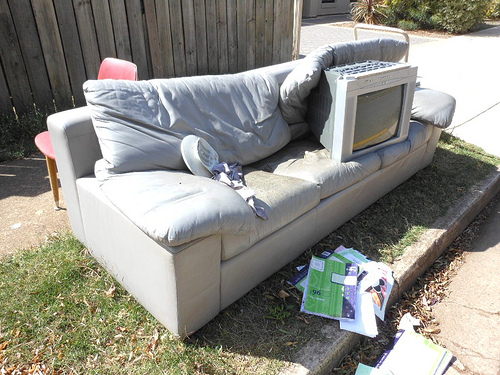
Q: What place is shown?
A: It is a street.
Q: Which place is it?
A: It is a street.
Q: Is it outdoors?
A: Yes, it is outdoors.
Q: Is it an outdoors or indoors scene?
A: It is outdoors.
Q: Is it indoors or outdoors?
A: It is outdoors.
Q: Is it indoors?
A: No, it is outdoors.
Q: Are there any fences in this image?
A: Yes, there is a fence.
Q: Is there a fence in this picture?
A: Yes, there is a fence.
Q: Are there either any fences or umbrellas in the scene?
A: Yes, there is a fence.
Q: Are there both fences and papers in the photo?
A: Yes, there are both a fence and papers.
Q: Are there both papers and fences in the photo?
A: Yes, there are both a fence and papers.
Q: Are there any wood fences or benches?
A: Yes, there is a wood fence.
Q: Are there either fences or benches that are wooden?
A: Yes, the fence is wooden.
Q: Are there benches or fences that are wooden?
A: Yes, the fence is wooden.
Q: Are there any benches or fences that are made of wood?
A: Yes, the fence is made of wood.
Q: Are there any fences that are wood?
A: Yes, there is a wood fence.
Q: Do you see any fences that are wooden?
A: Yes, there is a fence that is wooden.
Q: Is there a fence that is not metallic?
A: Yes, there is a wooden fence.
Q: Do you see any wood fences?
A: Yes, there is a fence that is made of wood.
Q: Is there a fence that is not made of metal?
A: Yes, there is a fence that is made of wood.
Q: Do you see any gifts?
A: No, there are no gifts.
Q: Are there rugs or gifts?
A: No, there are no gifts or rugs.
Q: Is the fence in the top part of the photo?
A: Yes, the fence is in the top of the image.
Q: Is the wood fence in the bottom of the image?
A: No, the fence is in the top of the image.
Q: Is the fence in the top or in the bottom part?
A: The fence is in the top of the image.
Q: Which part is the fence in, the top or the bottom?
A: The fence is in the top of the image.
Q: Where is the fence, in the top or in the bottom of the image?
A: The fence is in the top of the image.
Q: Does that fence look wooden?
A: Yes, the fence is wooden.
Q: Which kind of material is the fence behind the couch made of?
A: The fence is made of wood.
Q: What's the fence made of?
A: The fence is made of wood.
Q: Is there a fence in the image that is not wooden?
A: No, there is a fence but it is wooden.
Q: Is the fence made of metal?
A: No, the fence is made of wood.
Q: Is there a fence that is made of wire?
A: No, there is a fence but it is made of wood.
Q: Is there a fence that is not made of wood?
A: No, there is a fence but it is made of wood.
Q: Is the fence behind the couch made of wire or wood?
A: The fence is made of wood.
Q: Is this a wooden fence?
A: Yes, this is a wooden fence.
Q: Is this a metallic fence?
A: No, this is a wooden fence.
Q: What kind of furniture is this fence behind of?
A: The fence is behind the couch.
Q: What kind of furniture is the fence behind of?
A: The fence is behind the couch.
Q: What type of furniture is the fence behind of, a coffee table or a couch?
A: The fence is behind a couch.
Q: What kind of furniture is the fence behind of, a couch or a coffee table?
A: The fence is behind a couch.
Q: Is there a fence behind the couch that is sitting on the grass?
A: Yes, there is a fence behind the couch.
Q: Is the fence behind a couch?
A: Yes, the fence is behind a couch.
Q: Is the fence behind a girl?
A: No, the fence is behind a couch.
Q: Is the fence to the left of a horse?
A: No, the fence is to the left of a pillow.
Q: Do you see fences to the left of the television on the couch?
A: Yes, there is a fence to the left of the TV.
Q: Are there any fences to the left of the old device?
A: Yes, there is a fence to the left of the TV.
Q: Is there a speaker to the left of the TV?
A: No, there is a fence to the left of the TV.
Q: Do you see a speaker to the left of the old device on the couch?
A: No, there is a fence to the left of the TV.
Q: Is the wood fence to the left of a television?
A: Yes, the fence is to the left of a television.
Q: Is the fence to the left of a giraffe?
A: No, the fence is to the left of a television.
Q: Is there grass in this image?
A: Yes, there is grass.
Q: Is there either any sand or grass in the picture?
A: Yes, there is grass.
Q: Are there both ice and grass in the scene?
A: No, there is grass but no ice.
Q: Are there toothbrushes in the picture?
A: No, there are no toothbrushes.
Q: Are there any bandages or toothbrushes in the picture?
A: No, there are no toothbrushes or bandages.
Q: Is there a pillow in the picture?
A: Yes, there is a pillow.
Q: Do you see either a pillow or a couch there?
A: Yes, there is a pillow.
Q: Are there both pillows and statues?
A: No, there is a pillow but no statues.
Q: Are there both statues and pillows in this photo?
A: No, there is a pillow but no statues.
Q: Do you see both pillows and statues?
A: No, there is a pillow but no statues.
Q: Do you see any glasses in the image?
A: No, there are no glasses.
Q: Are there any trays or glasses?
A: No, there are no glasses or trays.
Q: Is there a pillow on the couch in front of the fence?
A: Yes, there is a pillow on the couch.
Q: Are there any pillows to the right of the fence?
A: Yes, there is a pillow to the right of the fence.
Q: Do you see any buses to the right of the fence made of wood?
A: No, there is a pillow to the right of the fence.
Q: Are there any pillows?
A: Yes, there is a pillow.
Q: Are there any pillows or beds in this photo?
A: Yes, there is a pillow.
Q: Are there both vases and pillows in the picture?
A: No, there is a pillow but no vases.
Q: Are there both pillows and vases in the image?
A: No, there is a pillow but no vases.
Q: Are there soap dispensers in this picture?
A: No, there are no soap dispensers.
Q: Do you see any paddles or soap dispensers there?
A: No, there are no soap dispensers or paddles.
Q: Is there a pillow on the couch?
A: Yes, there is a pillow on the couch.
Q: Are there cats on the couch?
A: No, there is a pillow on the couch.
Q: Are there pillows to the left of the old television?
A: Yes, there is a pillow to the left of the television.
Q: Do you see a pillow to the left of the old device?
A: Yes, there is a pillow to the left of the television.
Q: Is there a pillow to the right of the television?
A: No, the pillow is to the left of the television.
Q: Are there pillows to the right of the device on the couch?
A: No, the pillow is to the left of the television.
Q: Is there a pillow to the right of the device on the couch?
A: No, the pillow is to the left of the television.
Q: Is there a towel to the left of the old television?
A: No, there is a pillow to the left of the TV.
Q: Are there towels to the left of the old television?
A: No, there is a pillow to the left of the TV.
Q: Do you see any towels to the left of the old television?
A: No, there is a pillow to the left of the TV.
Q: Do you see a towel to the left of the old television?
A: No, there is a pillow to the left of the TV.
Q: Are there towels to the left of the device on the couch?
A: No, there is a pillow to the left of the TV.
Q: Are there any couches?
A: Yes, there is a couch.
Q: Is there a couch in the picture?
A: Yes, there is a couch.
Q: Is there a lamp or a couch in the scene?
A: Yes, there is a couch.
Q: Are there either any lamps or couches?
A: Yes, there is a couch.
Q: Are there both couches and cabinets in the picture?
A: No, there is a couch but no cabinets.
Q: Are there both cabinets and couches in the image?
A: No, there is a couch but no cabinets.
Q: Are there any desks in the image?
A: No, there are no desks.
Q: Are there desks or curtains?
A: No, there are no desks or curtains.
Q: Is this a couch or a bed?
A: This is a couch.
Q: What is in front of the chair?
A: The couch is in front of the chair.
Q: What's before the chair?
A: The couch is in front of the chair.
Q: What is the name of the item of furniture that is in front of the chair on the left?
A: The piece of furniture is a couch.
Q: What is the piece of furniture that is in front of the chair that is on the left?
A: The piece of furniture is a couch.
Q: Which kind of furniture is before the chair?
A: The piece of furniture is a couch.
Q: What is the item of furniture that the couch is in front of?
A: The piece of furniture is a chair.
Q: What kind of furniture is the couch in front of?
A: The couch is in front of the chair.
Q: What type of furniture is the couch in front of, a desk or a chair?
A: The couch is in front of a chair.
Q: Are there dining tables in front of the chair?
A: No, there is a couch in front of the chair.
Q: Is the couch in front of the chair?
A: Yes, the couch is in front of the chair.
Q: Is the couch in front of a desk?
A: No, the couch is in front of the chair.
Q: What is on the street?
A: The couch is on the street.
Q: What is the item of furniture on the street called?
A: The piece of furniture is a couch.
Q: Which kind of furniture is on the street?
A: The piece of furniture is a couch.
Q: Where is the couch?
A: The couch is on the street.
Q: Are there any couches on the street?
A: Yes, there is a couch on the street.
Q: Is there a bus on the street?
A: No, there is a couch on the street.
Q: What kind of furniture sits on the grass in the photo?
A: The piece of furniture is a couch.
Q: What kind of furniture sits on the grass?
A: The piece of furniture is a couch.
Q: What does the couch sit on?
A: The couch sits on the grass.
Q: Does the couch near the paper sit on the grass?
A: Yes, the couch sits on the grass.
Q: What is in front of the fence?
A: The couch is in front of the fence.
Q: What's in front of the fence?
A: The couch is in front of the fence.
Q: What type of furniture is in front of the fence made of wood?
A: The piece of furniture is a couch.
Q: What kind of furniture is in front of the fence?
A: The piece of furniture is a couch.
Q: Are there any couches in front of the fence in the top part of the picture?
A: Yes, there is a couch in front of the fence.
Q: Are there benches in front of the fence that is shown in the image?
A: No, there is a couch in front of the fence.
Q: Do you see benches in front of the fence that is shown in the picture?
A: No, there is a couch in front of the fence.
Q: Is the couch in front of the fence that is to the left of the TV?
A: Yes, the couch is in front of the fence.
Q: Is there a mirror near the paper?
A: No, there is a couch near the paper.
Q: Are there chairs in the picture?
A: Yes, there is a chair.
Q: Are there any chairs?
A: Yes, there is a chair.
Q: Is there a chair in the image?
A: Yes, there is a chair.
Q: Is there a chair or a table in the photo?
A: Yes, there is a chair.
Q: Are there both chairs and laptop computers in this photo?
A: No, there is a chair but no laptops.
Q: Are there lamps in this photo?
A: No, there are no lamps.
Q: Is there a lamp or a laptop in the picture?
A: No, there are no lamps or laptops.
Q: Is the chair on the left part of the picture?
A: Yes, the chair is on the left of the image.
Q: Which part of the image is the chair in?
A: The chair is on the left of the image.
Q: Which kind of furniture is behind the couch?
A: The piece of furniture is a chair.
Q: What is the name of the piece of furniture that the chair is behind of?
A: The piece of furniture is a couch.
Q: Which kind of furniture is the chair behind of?
A: The chair is behind the couch.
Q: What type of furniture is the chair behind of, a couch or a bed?
A: The chair is behind a couch.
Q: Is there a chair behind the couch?
A: Yes, there is a chair behind the couch.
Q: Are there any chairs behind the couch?
A: Yes, there is a chair behind the couch.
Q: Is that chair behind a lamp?
A: No, the chair is behind the couch.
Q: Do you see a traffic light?
A: No, there are no traffic lights.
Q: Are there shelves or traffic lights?
A: No, there are no traffic lights or shelves.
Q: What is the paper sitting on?
A: The paper is sitting on the grass.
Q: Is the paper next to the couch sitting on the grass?
A: Yes, the paper is sitting on the grass.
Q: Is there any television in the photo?
A: Yes, there is a television.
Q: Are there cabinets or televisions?
A: Yes, there is a television.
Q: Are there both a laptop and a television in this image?
A: No, there is a television but no laptops.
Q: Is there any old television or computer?
A: Yes, there is an old television.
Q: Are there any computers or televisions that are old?
A: Yes, the television is old.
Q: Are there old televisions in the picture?
A: Yes, there is an old television.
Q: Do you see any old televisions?
A: Yes, there is an old television.